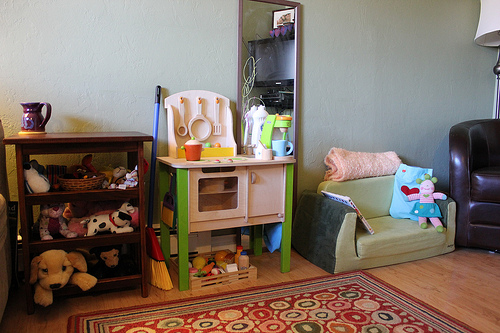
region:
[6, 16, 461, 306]
childs play area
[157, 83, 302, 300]
small toy kitchen playset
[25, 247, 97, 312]
large brown stuffed dog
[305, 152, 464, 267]
child sized green couch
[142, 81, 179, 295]
red, blue and yellow broom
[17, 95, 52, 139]
scented wax melter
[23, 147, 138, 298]
shelving full of toys and stuffed animals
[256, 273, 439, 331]
red green and white floor rug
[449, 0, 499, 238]
dark leather couch near lamp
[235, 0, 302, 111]
mirror reflecting television and wall art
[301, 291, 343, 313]
rug on the floor.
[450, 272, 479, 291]
floor made of wood.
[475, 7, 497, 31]
lamp shade on pole.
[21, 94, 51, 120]
pot on the shelf.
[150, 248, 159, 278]
thistles of the broom.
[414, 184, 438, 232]
stuffed animal on the chair.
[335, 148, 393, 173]
blanket on the chair.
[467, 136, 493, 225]
leather chair against the wall.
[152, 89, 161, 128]
handle of the broom.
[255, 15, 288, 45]
mirror leaning on the wall.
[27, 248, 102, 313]
a stuffed dog on a shelf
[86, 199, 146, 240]
a stuffed dog on a shelf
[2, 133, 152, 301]
a shelf full of toys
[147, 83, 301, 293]
a child's play kitchen with all the necessities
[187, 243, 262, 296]
a crate of play food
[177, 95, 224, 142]
play cooking pan, cooking spoon, and spatula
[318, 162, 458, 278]
a child's play sofa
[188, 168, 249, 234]
an oven door of a toy kitchen stuff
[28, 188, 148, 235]
a shelf with stuffed animals on it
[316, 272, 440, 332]
an area rug on a floor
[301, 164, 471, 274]
child's couch with toys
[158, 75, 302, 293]
children's kitchen with oven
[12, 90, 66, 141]
cup sitting on a bookshelf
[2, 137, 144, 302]
stuffed animals in a bookcase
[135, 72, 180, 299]
broom leaning against wall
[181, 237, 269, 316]
children's toy food in a box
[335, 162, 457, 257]
stuffed doll sitting on a couch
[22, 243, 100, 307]
stuffed dog sitting in a bookcase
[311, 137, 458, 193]
blanket sitting on a child's couch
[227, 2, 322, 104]
mirror hanging on the wall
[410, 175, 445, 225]
stuffed doll on chair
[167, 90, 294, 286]
play kitchen on floor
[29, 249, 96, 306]
brown stuffed dog on shelf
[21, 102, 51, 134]
ceramic pitcher on shelf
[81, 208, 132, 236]
white and black stuffed dog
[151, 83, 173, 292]
toy broom on floor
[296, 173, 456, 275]
green childs sofa on floor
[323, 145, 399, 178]
pink blanket on chair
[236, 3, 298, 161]
mirror hanging on wall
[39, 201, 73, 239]
grey stuffed animal on shelf